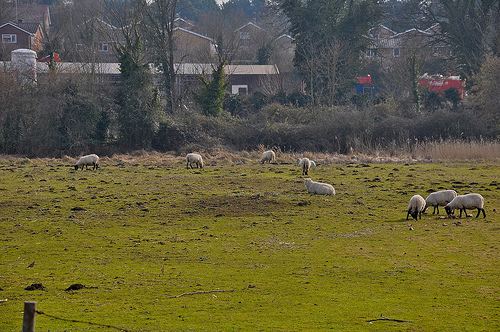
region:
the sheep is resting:
[298, 171, 341, 202]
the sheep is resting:
[291, 158, 340, 218]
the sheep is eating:
[398, 195, 424, 232]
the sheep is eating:
[424, 201, 454, 223]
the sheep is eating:
[73, 145, 105, 177]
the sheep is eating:
[174, 145, 216, 171]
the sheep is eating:
[251, 145, 281, 163]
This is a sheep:
[180, 142, 210, 179]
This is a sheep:
[69, 143, 104, 187]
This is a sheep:
[299, 169, 344, 207]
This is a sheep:
[401, 188, 432, 223]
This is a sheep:
[439, 185, 496, 224]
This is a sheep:
[421, 173, 458, 220]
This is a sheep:
[296, 151, 323, 179]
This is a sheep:
[255, 140, 283, 175]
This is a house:
[224, 8, 274, 62]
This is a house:
[398, 54, 483, 131]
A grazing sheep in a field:
[444, 190, 489, 220]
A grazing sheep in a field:
[423, 184, 456, 213]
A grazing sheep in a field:
[403, 193, 426, 224]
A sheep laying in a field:
[303, 175, 334, 196]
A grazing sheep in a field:
[299, 154, 313, 176]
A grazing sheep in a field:
[261, 145, 276, 164]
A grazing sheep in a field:
[182, 150, 208, 170]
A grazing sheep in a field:
[73, 152, 100, 172]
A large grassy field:
[0, 155, 498, 330]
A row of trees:
[1, 8, 499, 150]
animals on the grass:
[380, 175, 493, 238]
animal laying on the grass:
[293, 169, 342, 209]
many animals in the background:
[53, 109, 352, 245]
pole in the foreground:
[13, 293, 47, 330]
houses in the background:
[120, 20, 291, 70]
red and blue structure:
[333, 55, 485, 114]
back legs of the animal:
[475, 205, 489, 219]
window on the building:
[0, 28, 22, 50]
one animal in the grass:
[159, 140, 219, 195]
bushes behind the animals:
[141, 123, 243, 149]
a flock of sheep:
[35, 141, 490, 243]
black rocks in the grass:
[22, 276, 91, 297]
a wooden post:
[18, 299, 43, 328]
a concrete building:
[4, 58, 273, 105]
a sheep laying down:
[292, 176, 338, 193]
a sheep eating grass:
[73, 150, 104, 174]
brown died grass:
[357, 133, 499, 160]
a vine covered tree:
[114, 34, 159, 153]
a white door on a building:
[232, 83, 248, 98]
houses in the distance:
[59, 14, 450, 53]